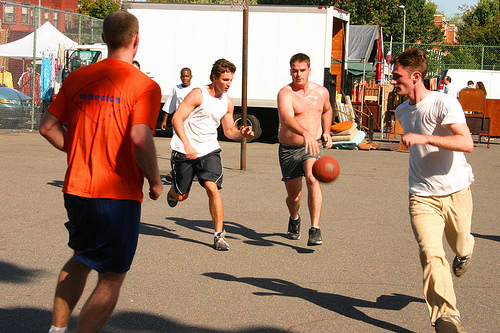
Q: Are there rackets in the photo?
A: No, there are no rackets.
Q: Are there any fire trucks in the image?
A: No, there are no fire trucks.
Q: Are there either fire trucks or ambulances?
A: No, there are no fire trucks or ambulances.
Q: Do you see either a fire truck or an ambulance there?
A: No, there are no fire trucks or ambulances.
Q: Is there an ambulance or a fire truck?
A: No, there are no fire trucks or ambulances.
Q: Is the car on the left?
A: Yes, the car is on the left of the image.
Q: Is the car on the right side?
A: No, the car is on the left of the image.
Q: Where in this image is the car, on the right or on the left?
A: The car is on the left of the image.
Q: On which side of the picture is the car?
A: The car is on the left of the image.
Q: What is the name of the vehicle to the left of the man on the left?
A: The vehicle is a car.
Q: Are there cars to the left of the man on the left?
A: Yes, there is a car to the left of the man.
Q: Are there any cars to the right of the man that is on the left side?
A: No, the car is to the left of the man.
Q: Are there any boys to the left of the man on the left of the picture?
A: No, there is a car to the left of the man.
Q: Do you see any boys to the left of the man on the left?
A: No, there is a car to the left of the man.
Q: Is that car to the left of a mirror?
A: No, the car is to the left of the man.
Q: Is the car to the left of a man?
A: Yes, the car is to the left of a man.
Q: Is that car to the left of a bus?
A: No, the car is to the left of a man.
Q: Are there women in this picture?
A: No, there are no women.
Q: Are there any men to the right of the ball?
A: Yes, there is a man to the right of the ball.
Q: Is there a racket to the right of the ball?
A: No, there is a man to the right of the ball.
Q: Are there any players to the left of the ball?
A: No, there is a man to the left of the ball.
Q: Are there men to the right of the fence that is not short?
A: Yes, there is a man to the right of the fence.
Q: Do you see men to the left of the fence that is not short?
A: No, the man is to the right of the fence.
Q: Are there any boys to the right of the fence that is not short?
A: No, there is a man to the right of the fence.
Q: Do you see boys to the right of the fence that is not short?
A: No, there is a man to the right of the fence.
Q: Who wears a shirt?
A: The man wears a shirt.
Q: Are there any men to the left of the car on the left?
A: No, the man is to the right of the car.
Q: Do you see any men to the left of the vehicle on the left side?
A: No, the man is to the right of the car.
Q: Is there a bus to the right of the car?
A: No, there is a man to the right of the car.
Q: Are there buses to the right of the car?
A: No, there is a man to the right of the car.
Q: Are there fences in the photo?
A: Yes, there is a fence.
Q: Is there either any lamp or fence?
A: Yes, there is a fence.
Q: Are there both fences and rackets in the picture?
A: No, there is a fence but no rackets.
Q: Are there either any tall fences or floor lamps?
A: Yes, there is a tall fence.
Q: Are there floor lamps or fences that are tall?
A: Yes, the fence is tall.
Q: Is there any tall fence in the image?
A: Yes, there is a tall fence.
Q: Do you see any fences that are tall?
A: Yes, there is a fence that is tall.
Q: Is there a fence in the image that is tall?
A: Yes, there is a fence that is tall.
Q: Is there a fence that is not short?
A: Yes, there is a tall fence.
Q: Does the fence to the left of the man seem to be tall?
A: Yes, the fence is tall.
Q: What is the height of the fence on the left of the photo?
A: The fence is tall.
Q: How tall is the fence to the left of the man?
A: The fence is tall.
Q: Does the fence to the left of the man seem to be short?
A: No, the fence is tall.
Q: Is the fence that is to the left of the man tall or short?
A: The fence is tall.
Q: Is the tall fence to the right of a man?
A: No, the fence is to the left of a man.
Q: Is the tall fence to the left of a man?
A: Yes, the fence is to the left of a man.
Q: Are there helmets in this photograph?
A: No, there are no helmets.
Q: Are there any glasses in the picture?
A: No, there are no glasses.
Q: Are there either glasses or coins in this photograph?
A: No, there are no glasses or coins.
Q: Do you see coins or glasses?
A: No, there are no glasses or coins.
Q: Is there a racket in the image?
A: No, there are no rackets.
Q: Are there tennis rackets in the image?
A: No, there are no tennis rackets.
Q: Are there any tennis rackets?
A: No, there are no tennis rackets.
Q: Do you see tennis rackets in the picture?
A: No, there are no tennis rackets.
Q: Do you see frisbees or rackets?
A: No, there are no rackets or frisbees.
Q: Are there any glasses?
A: No, there are no glasses.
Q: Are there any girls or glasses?
A: No, there are no glasses or girls.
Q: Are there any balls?
A: Yes, there is a ball.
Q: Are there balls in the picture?
A: Yes, there is a ball.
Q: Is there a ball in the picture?
A: Yes, there is a ball.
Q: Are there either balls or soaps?
A: Yes, there is a ball.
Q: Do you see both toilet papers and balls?
A: No, there is a ball but no toilet papers.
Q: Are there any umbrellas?
A: No, there are no umbrellas.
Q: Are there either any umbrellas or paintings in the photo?
A: No, there are no umbrellas or paintings.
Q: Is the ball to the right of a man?
A: Yes, the ball is to the right of a man.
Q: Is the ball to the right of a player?
A: No, the ball is to the right of a man.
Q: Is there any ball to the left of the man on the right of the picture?
A: Yes, there is a ball to the left of the man.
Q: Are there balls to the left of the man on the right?
A: Yes, there is a ball to the left of the man.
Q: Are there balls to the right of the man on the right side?
A: No, the ball is to the left of the man.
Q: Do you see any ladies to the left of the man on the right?
A: No, there is a ball to the left of the man.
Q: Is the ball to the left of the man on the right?
A: Yes, the ball is to the left of the man.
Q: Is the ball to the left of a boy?
A: No, the ball is to the left of the man.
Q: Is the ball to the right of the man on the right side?
A: No, the ball is to the left of the man.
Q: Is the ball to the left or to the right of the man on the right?
A: The ball is to the left of the man.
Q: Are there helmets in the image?
A: No, there are no helmets.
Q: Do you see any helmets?
A: No, there are no helmets.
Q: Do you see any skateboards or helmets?
A: No, there are no helmets or skateboards.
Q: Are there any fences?
A: Yes, there is a fence.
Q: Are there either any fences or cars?
A: Yes, there is a fence.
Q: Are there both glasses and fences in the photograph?
A: No, there is a fence but no glasses.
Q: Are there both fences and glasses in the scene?
A: No, there is a fence but no glasses.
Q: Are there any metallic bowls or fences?
A: Yes, there is a metal fence.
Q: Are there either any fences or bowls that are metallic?
A: Yes, the fence is metallic.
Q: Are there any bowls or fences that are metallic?
A: Yes, the fence is metallic.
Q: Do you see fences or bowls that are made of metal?
A: Yes, the fence is made of metal.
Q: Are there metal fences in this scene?
A: Yes, there is a metal fence.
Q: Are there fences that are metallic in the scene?
A: Yes, there is a metal fence.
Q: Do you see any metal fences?
A: Yes, there is a metal fence.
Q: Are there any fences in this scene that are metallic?
A: Yes, there is a fence that is metallic.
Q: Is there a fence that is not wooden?
A: Yes, there is a metallic fence.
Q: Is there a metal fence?
A: Yes, there is a fence that is made of metal.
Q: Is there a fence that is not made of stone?
A: Yes, there is a fence that is made of metal.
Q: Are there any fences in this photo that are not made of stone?
A: Yes, there is a fence that is made of metal.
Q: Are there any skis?
A: No, there are no skis.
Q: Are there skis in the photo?
A: No, there are no skis.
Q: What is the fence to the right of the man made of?
A: The fence is made of metal.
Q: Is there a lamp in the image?
A: No, there are no lamps.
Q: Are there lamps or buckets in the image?
A: No, there are no lamps or buckets.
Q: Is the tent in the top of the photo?
A: Yes, the tent is in the top of the image.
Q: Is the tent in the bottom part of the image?
A: No, the tent is in the top of the image.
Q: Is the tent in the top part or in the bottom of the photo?
A: The tent is in the top of the image.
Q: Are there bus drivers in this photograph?
A: No, there are no bus drivers.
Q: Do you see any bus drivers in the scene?
A: No, there are no bus drivers.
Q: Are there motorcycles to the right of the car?
A: No, there is a man to the right of the car.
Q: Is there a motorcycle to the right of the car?
A: No, there is a man to the right of the car.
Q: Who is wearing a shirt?
A: The man is wearing a shirt.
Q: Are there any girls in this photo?
A: No, there are no girls.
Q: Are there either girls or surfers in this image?
A: No, there are no girls or surfers.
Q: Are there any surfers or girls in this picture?
A: No, there are no girls or surfers.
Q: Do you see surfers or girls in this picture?
A: No, there are no girls or surfers.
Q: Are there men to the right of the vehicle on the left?
A: Yes, there is a man to the right of the car.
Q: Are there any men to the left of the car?
A: No, the man is to the right of the car.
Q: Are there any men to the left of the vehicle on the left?
A: No, the man is to the right of the car.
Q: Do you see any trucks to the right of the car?
A: No, there is a man to the right of the car.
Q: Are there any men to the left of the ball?
A: Yes, there is a man to the left of the ball.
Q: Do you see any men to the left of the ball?
A: Yes, there is a man to the left of the ball.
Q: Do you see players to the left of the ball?
A: No, there is a man to the left of the ball.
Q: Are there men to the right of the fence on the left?
A: Yes, there is a man to the right of the fence.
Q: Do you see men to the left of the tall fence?
A: No, the man is to the right of the fence.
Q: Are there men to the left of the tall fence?
A: No, the man is to the right of the fence.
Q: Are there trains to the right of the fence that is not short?
A: No, there is a man to the right of the fence.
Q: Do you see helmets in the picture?
A: No, there are no helmets.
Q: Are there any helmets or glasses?
A: No, there are no helmets or glasses.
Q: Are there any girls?
A: No, there are no girls.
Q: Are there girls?
A: No, there are no girls.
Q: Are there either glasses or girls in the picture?
A: No, there are no girls or glasses.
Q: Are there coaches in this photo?
A: No, there are no coaches.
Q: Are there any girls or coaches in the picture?
A: No, there are no coaches or girls.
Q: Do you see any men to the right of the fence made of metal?
A: No, the man is to the left of the fence.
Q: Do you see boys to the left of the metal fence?
A: No, there is a man to the left of the fence.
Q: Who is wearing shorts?
A: The man is wearing shorts.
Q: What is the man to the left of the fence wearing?
A: The man is wearing shorts.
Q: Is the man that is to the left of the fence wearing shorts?
A: Yes, the man is wearing shorts.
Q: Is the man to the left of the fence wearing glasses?
A: No, the man is wearing shorts.